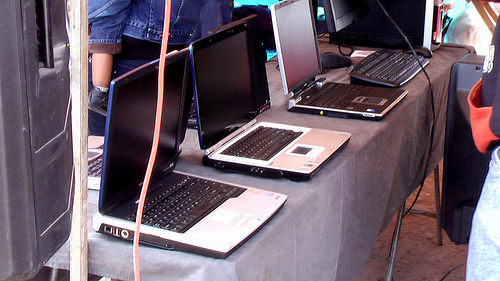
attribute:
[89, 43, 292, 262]
laptop — displayed, open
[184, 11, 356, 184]
laptop — displayed, open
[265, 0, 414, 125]
laptop — displayed, open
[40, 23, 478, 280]
table — grey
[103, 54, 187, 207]
screen — black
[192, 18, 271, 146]
screen — black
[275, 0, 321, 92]
screen — black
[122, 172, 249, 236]
keyboard — black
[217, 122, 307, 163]
keyboard — black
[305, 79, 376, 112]
keyboard — black